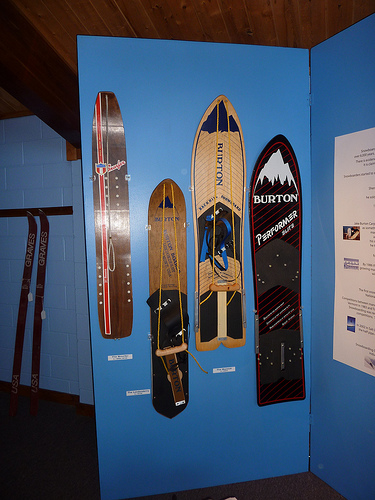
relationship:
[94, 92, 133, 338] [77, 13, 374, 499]
skateboard handing on board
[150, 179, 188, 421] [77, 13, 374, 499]
skateboard handing on board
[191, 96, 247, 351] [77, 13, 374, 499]
skateboard handing on board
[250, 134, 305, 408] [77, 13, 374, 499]
skateboard handing on board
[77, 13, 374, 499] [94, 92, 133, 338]
board holding skateboard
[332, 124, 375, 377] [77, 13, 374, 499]
paper on board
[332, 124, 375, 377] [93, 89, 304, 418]
paper near skateboards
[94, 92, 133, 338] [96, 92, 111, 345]
skateboard with red line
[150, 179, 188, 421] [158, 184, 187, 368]
skateboard with thread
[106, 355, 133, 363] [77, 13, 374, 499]
label on board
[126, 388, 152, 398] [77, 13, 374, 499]
label on board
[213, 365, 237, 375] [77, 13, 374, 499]
label on board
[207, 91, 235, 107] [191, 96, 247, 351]
nose of skateboard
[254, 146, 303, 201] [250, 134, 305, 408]
mountain on skateboard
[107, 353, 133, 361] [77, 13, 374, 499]
label on board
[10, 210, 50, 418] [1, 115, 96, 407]
ski on wall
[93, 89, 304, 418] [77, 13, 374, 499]
skateboards on board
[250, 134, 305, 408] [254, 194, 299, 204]
skateboard with burton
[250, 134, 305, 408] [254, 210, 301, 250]
skateboard with performer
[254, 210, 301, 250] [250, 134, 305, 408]
performer on skateboard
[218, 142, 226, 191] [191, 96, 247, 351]
ripton on skateboard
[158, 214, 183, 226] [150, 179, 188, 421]
barton on skateboard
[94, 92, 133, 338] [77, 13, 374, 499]
skateboard on board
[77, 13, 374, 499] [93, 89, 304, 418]
board with skateboards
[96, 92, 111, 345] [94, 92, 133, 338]
line on skateboard